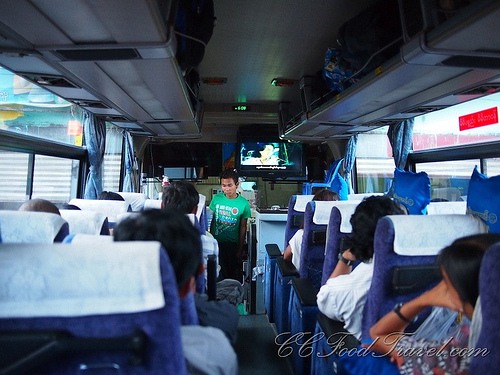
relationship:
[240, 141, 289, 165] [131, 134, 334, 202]
video in front of vehicle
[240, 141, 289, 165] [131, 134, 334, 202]
screen in front of vehicle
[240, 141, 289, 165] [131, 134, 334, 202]
tv in front of vehicle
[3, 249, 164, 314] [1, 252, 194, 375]
white cloth on blue seat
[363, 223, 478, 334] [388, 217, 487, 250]
blue seat with white cloth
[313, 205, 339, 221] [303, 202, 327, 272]
white cloth on blue seat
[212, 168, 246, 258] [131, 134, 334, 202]
man in front of vehicle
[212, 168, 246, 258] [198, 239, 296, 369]
man in aisle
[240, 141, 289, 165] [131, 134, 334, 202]
tv hanging in front of vehicle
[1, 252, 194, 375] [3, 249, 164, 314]
seat has white headrest cover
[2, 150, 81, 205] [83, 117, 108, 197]
window has curtains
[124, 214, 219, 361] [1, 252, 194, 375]
man sitting in bus seat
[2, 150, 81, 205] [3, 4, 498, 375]
window on vehicle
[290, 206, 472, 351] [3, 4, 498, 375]
people on bus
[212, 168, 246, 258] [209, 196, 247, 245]
man in green top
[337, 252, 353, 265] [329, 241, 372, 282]
watch on mans hand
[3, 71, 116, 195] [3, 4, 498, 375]
open windows on bus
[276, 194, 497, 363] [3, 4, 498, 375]
row of seats on bus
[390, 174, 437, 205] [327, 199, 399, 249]
pillows on seats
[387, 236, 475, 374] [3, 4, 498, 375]
woman sitting on bus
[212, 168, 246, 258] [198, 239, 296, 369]
man standing in aisle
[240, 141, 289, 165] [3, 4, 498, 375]
television screen on bus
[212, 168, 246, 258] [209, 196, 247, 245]
person in green shirt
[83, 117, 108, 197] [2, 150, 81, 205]
curtains hanging on window